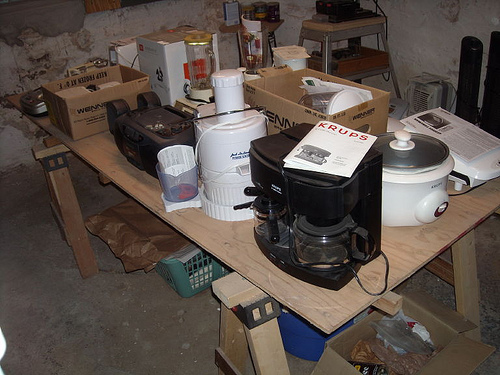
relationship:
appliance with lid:
[371, 130, 454, 227] [368, 125, 449, 179]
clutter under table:
[87, 204, 212, 306] [9, 49, 496, 336]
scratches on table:
[252, 266, 349, 334] [2, 66, 497, 373]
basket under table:
[154, 244, 230, 297] [9, 49, 496, 336]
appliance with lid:
[375, 126, 456, 231] [370, 120, 450, 175]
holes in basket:
[189, 262, 191, 267] [155, 245, 231, 296]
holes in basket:
[193, 258, 197, 263] [155, 245, 231, 296]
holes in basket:
[197, 254, 202, 263] [155, 245, 231, 296]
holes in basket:
[194, 265, 196, 272] [155, 245, 231, 296]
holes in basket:
[204, 260, 208, 265] [155, 245, 231, 296]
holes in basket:
[198, 276, 204, 280] [155, 245, 231, 296]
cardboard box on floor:
[304, 286, 496, 373] [2, 156, 499, 371]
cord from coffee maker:
[339, 218, 409, 345] [246, 121, 382, 291]